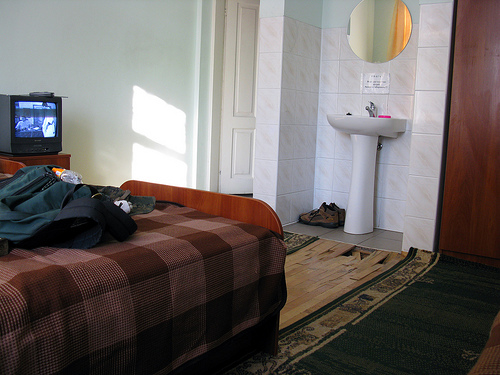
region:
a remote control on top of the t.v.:
[26, 90, 57, 97]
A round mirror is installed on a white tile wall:
[345, 1, 415, 63]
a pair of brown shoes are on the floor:
[296, 203, 348, 230]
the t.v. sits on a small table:
[1, 95, 64, 155]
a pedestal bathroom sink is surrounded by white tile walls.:
[326, 101, 408, 233]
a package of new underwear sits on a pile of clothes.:
[51, 165, 86, 186]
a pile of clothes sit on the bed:
[2, 161, 162, 255]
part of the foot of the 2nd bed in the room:
[1, 161, 26, 176]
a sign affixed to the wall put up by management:
[360, 73, 390, 96]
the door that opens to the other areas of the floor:
[221, 0, 253, 200]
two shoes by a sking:
[296, 194, 350, 230]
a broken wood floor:
[315, 230, 411, 277]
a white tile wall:
[275, 25, 330, 101]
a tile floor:
[287, 202, 402, 243]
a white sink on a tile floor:
[315, 92, 406, 242]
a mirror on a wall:
[342, 0, 413, 72]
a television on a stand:
[4, 83, 78, 159]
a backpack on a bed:
[3, 151, 139, 259]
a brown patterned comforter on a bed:
[5, 197, 282, 371]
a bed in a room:
[1, 179, 309, 370]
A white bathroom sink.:
[325, 93, 405, 241]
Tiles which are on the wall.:
[280, 36, 320, 191]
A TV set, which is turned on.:
[2, 95, 68, 156]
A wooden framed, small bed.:
[1, 177, 296, 368]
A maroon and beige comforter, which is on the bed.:
[2, 210, 272, 341]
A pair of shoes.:
[288, 200, 349, 233]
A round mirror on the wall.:
[340, 2, 417, 64]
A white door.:
[224, 3, 264, 200]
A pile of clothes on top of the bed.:
[0, 167, 175, 277]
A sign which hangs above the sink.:
[356, 67, 397, 97]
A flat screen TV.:
[2, 66, 100, 177]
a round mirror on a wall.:
[332, 0, 419, 84]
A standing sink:
[283, 105, 448, 256]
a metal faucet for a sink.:
[355, 91, 402, 128]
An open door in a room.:
[211, 4, 261, 204]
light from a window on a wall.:
[120, 91, 191, 176]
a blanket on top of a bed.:
[0, 154, 186, 291]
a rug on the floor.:
[318, 274, 379, 346]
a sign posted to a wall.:
[343, 61, 397, 104]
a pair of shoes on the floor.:
[292, 193, 347, 245]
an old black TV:
[2, 90, 64, 154]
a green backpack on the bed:
[2, 162, 138, 253]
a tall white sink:
[323, 100, 409, 237]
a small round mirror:
[345, 0, 415, 67]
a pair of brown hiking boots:
[297, 199, 347, 229]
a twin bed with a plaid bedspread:
[2, 176, 283, 372]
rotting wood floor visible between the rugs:
[280, 237, 405, 330]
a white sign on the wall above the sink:
[360, 70, 390, 94]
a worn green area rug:
[221, 246, 498, 372]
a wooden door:
[432, 0, 498, 265]